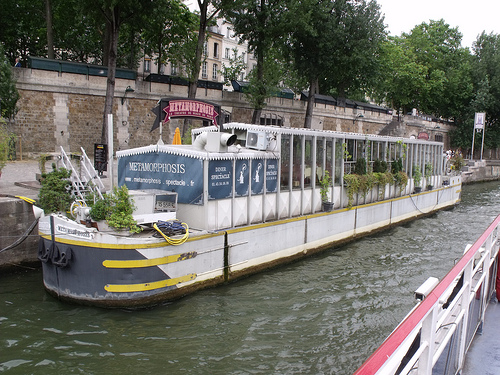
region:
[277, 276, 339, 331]
water next to the structure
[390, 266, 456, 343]
red and white fence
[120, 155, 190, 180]
white word on the structure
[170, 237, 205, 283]
yellow and white structure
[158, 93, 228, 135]
sign next to the structure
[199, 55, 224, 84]
windows on the building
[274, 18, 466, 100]
trees above the water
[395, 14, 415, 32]
sky above the trees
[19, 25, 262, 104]
branches of the trees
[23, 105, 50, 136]
brick wall in the photo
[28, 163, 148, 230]
green vegetation on boat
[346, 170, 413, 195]
green vegetation on boat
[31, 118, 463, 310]
long blue and white boat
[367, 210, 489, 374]
red and white safety fence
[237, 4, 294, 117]
tall green leafy tree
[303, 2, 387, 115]
tall green leafy tree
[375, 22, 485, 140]
tall green leafy tree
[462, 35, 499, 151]
tall green leafy tree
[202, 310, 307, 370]
ripples on surface of water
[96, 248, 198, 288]
yellow strip in front of boat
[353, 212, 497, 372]
second boat passing by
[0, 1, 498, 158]
green trees line the heavily used river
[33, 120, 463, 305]
second boat is not moving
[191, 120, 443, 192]
appears to be enclosed with windows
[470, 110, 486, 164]
tall sign in the distance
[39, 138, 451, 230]
lots of living plants grow on the boat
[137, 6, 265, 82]
buildings line the side of the river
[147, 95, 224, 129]
banner telling name of boat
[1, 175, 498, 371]
the river is full of very dark water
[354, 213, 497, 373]
red railing on second boat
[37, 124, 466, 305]
blue and white boat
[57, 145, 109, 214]
white metal stairs to boat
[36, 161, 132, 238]
green plants on boat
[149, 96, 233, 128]
black and red sign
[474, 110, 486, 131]
white sign on curb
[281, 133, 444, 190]
glass windows on boat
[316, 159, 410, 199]
green plants on windows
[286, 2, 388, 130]
tree with green leaves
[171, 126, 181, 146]
yellow patio umbrella on sidewalk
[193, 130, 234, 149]
white metal exhaust tube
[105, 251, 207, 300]
The yellow stripes on the boat.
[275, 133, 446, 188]
The windows on the side of the boat.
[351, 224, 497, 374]
The red paint on the railing.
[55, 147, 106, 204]
The white stairs on the left.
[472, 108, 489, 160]
The white sign on the dock.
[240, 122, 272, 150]
The fan/air conditioner unit on the top of the boat's roof.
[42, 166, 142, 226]
The small trees on the front of the boat.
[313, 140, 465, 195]
The small plants/trees on the side of the boat.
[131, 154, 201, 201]
The big blue sign on the front of the boat.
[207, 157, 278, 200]
The four blue signs on the side of the boat.